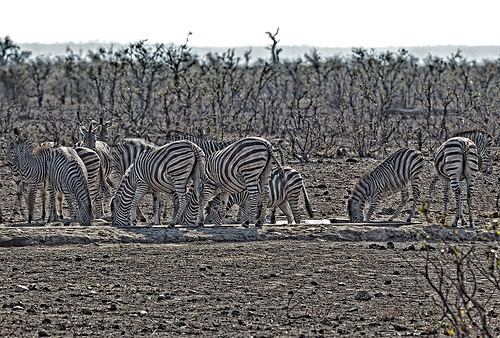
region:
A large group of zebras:
[6, 117, 482, 244]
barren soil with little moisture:
[3, 249, 240, 336]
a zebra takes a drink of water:
[338, 144, 430, 228]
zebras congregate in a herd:
[6, 122, 314, 243]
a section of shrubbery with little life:
[239, 53, 487, 130]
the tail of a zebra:
[298, 176, 320, 221]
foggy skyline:
[28, 26, 182, 39]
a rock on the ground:
[353, 287, 373, 302]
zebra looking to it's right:
[430, 123, 498, 230]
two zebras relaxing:
[334, 133, 492, 238]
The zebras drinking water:
[7, 129, 489, 228]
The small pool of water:
[3, 217, 455, 244]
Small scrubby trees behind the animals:
[1, 27, 491, 151]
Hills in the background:
[13, 37, 499, 57]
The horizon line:
[3, 34, 498, 63]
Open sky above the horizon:
[2, 0, 496, 44]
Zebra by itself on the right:
[428, 132, 499, 232]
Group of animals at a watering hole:
[7, 112, 479, 227]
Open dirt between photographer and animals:
[2, 246, 499, 337]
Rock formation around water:
[2, 227, 499, 247]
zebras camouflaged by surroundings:
[7, 107, 482, 255]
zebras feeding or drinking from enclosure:
[20, 125, 480, 245]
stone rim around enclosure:
[20, 207, 481, 258]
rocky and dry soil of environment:
[67, 250, 402, 330]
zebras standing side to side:
[102, 125, 282, 240]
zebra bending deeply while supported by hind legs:
[335, 125, 425, 230]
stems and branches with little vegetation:
[100, 20, 405, 140]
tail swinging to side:
[210, 125, 295, 220]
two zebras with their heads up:
[5, 115, 105, 230]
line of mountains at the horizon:
[52, 10, 479, 110]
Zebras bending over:
[28, 132, 493, 247]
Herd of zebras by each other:
[14, 126, 496, 253]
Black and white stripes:
[81, 140, 454, 237]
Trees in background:
[50, 65, 433, 134]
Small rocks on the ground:
[83, 243, 322, 335]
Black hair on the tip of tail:
[287, 189, 342, 215]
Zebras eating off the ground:
[43, 127, 326, 257]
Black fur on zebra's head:
[344, 182, 359, 244]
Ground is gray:
[48, 255, 365, 315]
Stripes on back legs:
[446, 150, 481, 238]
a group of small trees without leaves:
[28, 60, 468, 121]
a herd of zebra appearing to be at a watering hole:
[16, 133, 434, 240]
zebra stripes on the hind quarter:
[227, 145, 266, 190]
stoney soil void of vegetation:
[13, 250, 161, 334]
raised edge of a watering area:
[9, 224, 488, 257]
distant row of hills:
[27, 25, 454, 77]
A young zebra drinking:
[335, 140, 429, 229]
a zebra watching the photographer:
[66, 108, 121, 167]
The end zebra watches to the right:
[426, 114, 498, 235]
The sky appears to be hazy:
[283, 1, 423, 65]